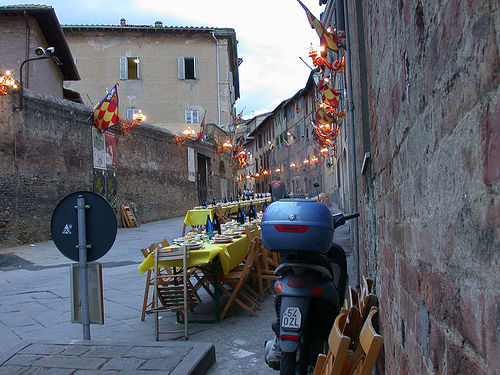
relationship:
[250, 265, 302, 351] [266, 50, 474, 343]
poster hanging on a wall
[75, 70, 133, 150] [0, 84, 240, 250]
flag on concrete wall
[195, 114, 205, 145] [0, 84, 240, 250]
flag on concrete wall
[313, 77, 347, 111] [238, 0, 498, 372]
flag on wall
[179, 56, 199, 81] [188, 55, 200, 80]
window with shutter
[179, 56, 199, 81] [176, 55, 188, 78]
window with shutter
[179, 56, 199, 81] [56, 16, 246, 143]
window on building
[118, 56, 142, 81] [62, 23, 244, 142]
window on building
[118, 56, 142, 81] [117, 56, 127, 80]
window with shutters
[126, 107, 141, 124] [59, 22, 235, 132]
window on building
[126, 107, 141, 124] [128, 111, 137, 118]
window with shutters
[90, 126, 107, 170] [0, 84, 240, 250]
poster hanging on concrete wall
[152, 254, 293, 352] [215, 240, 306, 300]
tables with chairs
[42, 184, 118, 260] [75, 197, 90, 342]
sign on post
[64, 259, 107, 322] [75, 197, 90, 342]
sign on post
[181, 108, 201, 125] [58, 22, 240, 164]
window of building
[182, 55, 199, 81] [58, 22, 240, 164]
window of building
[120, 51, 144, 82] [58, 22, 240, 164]
window of building